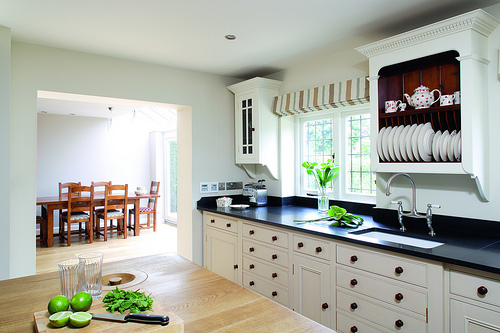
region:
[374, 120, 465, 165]
plates on the rack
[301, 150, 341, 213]
flower vase by the window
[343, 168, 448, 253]
sink and faucet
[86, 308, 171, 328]
a knife on the chopping board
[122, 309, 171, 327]
handle grip of the knife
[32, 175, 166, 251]
chairs and tables in the dinning room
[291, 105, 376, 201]
window in the kitchen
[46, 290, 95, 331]
Limes slice in half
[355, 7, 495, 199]
cabinet with white plates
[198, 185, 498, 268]
black marble counter top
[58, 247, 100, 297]
Two clear glasses on counter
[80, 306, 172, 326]
A chef's knife an cutting board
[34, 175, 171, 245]
A dining room table and chairs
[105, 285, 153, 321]
pile of green herbs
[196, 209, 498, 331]
White cabinest with handles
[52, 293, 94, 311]
Two whole limes on cutting board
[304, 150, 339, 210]
a vase with flowers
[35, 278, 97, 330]
Green limes on the cutting board.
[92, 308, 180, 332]
A black knife on the cutting board.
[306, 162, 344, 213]
Green flowers in the vase.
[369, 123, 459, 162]
Plates above the sink.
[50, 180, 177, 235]
Chairs and table in the other room.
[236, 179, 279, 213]
Toaster sitting on the kitchen counter.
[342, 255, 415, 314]
Knobs on the kitchen drawers.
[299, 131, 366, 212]
A vase in front of the window.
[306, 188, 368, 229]
Green flowers on the countertop.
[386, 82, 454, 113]
A teapot above the plates.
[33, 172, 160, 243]
The dining room table and chairs.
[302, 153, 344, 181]
The green flowers in a vase.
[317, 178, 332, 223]
The vase the green flowers are in.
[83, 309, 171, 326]
The knife on the cutting board.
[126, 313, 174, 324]
The handle of the knife.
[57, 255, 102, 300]
The glass cups on the center island.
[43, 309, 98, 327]
The lime that is cut in half.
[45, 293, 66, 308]
The lime on the left.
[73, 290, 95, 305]
The lime on the right.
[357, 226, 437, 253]
The basin of the sink.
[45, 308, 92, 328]
two halves of a lime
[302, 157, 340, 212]
green plant in glass vase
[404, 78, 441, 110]
white tea kettle with red dots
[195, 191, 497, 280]
long black counter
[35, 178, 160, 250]
long wood dining table and chairs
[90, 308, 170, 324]
knife with black handle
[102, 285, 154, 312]
green herb lleaves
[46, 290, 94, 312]
two whole green limes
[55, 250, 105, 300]
two empty glass cups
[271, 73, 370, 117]
white and tan window valance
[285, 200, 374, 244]
plants on the countertop